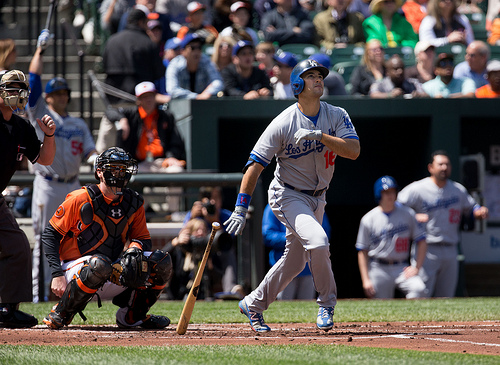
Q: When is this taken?
A: During the day.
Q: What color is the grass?
A: Green.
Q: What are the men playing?
A: Baseball.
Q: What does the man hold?
A: A bat.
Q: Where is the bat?
A: By the man.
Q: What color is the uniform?
A: White and blue.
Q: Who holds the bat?
A: A man.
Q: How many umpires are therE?
A: One.